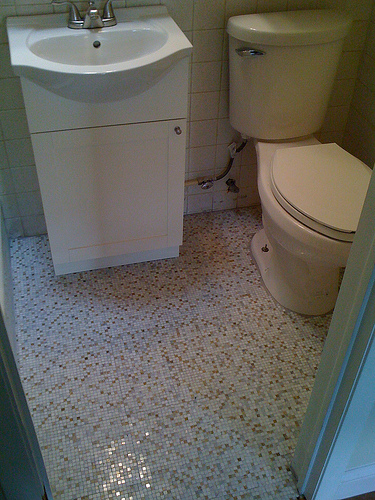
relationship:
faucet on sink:
[49, 0, 125, 30] [6, 5, 195, 105]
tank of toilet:
[225, 11, 351, 140] [225, 9, 373, 315]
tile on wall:
[1, 1, 374, 368] [5, 2, 361, 235]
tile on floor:
[46, 356, 50, 361] [23, 286, 303, 440]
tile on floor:
[62, 362, 66, 367] [23, 286, 303, 440]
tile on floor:
[87, 358, 90, 360] [23, 286, 303, 440]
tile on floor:
[82, 381, 93, 390] [23, 286, 303, 440]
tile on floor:
[113, 386, 116, 390] [23, 286, 303, 440]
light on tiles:
[97, 433, 156, 496] [94, 411, 148, 495]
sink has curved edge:
[2, 5, 195, 279] [11, 43, 193, 105]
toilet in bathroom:
[225, 9, 373, 315] [0, 0, 372, 498]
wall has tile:
[5, 2, 361, 235] [189, 149, 213, 170]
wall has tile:
[5, 2, 361, 235] [193, 29, 221, 63]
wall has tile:
[5, 2, 361, 235] [195, 63, 221, 90]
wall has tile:
[5, 2, 361, 235] [192, 92, 217, 118]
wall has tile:
[5, 2, 361, 235] [190, 121, 217, 146]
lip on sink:
[30, 42, 178, 107] [6, 5, 195, 105]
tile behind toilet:
[187, 16, 227, 161] [225, 9, 373, 315]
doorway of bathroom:
[292, 163, 373, 498] [0, 0, 372, 498]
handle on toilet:
[235, 42, 268, 60] [233, 42, 265, 58]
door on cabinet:
[29, 113, 184, 268] [27, 114, 192, 284]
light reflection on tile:
[100, 453, 154, 496] [99, 412, 158, 497]